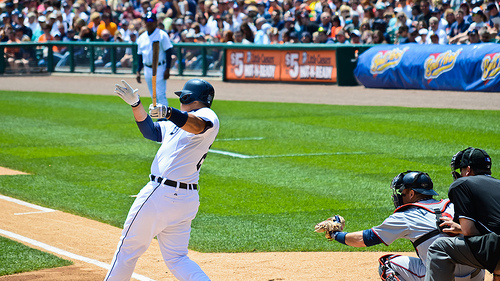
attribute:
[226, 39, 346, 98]
sign — orange, white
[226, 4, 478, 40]
fans — baseball, close, watching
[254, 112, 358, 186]
grass — green, cut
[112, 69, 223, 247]
player — playing, swinging, batting, dark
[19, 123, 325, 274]
field — green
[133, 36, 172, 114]
bat — brown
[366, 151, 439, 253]
catcher — playing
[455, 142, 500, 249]
umpire — sitting, behind, calling, watching, white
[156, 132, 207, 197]
shirt — white